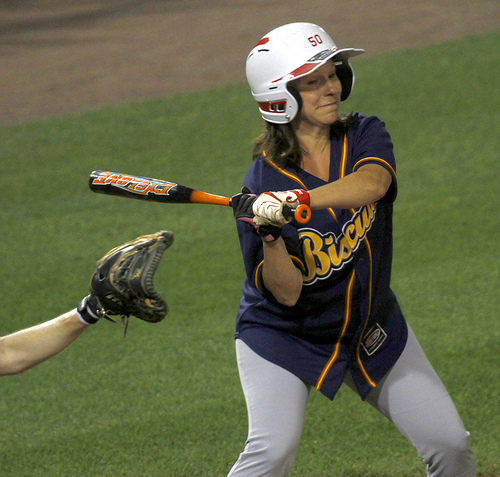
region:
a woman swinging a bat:
[85, 11, 447, 472]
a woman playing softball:
[95, 15, 473, 470]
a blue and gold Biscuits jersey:
[206, 118, 436, 385]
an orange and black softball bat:
[83, 159, 235, 215]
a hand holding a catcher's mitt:
[1, 227, 194, 394]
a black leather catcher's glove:
[70, 226, 182, 336]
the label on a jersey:
[358, 320, 385, 355]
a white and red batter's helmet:
[239, 21, 358, 126]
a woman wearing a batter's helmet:
[225, 18, 357, 155]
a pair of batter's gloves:
[228, 185, 302, 234]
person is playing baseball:
[86, 18, 478, 475]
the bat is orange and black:
[91, 170, 311, 222]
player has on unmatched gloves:
[223, 180, 312, 237]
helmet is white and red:
[246, 17, 366, 129]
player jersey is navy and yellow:
[229, 113, 410, 405]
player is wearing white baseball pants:
[214, 310, 477, 474]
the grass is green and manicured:
[1, 28, 499, 475]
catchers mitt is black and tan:
[73, 228, 174, 325]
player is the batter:
[226, 17, 475, 475]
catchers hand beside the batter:
[1, 231, 174, 372]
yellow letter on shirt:
[298, 223, 333, 287]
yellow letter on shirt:
[321, 230, 341, 267]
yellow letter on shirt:
[333, 231, 353, 263]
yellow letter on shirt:
[343, 219, 358, 247]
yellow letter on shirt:
[352, 206, 373, 234]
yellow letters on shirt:
[295, 201, 379, 285]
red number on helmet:
[306, 33, 317, 49]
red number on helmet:
[313, 33, 323, 45]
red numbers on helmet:
[304, 33, 324, 49]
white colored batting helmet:
[241, 20, 358, 124]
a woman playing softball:
[70, 12, 492, 462]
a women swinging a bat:
[73, 13, 407, 284]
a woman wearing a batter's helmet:
[236, 19, 368, 129]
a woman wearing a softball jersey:
[191, 22, 443, 416]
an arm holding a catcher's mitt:
[3, 215, 171, 411]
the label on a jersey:
[359, 325, 390, 354]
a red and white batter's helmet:
[225, 19, 364, 126]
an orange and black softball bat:
[73, 157, 243, 222]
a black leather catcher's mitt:
[68, 224, 190, 329]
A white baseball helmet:
[243, 17, 359, 124]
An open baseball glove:
[74, 226, 189, 328]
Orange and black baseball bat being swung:
[84, 165, 319, 223]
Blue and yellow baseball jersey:
[231, 111, 410, 400]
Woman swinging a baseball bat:
[86, 20, 480, 475]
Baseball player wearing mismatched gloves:
[229, 182, 310, 243]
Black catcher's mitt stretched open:
[77, 228, 171, 329]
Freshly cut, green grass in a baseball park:
[60, 371, 209, 471]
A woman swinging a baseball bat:
[89, 22, 484, 475]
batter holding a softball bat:
[195, 12, 476, 475]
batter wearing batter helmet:
[235, 15, 359, 127]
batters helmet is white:
[234, 14, 361, 122]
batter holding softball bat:
[84, 161, 313, 244]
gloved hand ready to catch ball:
[80, 224, 177, 334]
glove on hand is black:
[78, 228, 165, 330]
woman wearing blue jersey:
[218, 109, 425, 403]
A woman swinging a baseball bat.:
[83, 9, 462, 474]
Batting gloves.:
[223, 174, 310, 246]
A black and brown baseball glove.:
[89, 225, 182, 338]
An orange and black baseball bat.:
[82, 163, 307, 226]